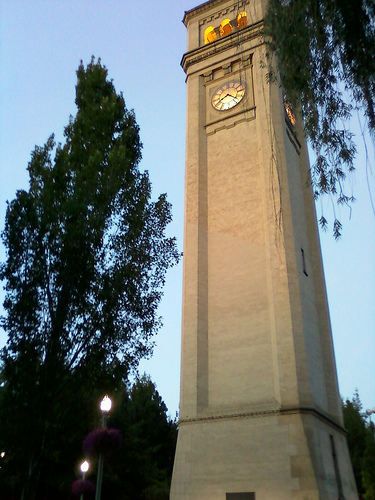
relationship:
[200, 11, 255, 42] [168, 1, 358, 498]
window on tower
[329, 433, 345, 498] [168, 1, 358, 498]
door leading to tower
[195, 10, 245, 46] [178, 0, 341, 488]
light coming from tower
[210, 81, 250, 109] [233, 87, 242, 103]
clock has roman numerals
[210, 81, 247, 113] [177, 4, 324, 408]
clock on a tower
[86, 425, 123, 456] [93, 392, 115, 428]
flowers are on a light pole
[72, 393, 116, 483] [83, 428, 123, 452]
light poles have flowers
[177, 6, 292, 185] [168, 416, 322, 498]
clock tower has a stone base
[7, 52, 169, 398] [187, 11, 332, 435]
tree beside a clock tower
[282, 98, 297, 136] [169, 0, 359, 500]
clock face on side of clock tower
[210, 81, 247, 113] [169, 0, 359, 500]
clock on side of clock tower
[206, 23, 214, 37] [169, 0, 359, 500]
light on top of clock tower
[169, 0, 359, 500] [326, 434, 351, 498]
clock tower has an entry door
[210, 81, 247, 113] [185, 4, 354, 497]
clock on a tower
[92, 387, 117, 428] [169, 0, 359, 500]
light near a clock tower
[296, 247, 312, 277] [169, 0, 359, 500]
window on a clock tower